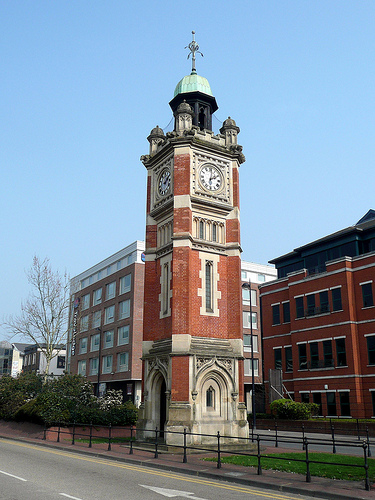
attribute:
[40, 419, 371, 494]
fence — metal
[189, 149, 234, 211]
clock — round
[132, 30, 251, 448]
tower — old, brick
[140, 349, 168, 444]
doorway — cement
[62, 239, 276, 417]
building — white, tan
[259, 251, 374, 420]
building — brown, red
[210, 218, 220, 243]
window — small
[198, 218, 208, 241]
window — small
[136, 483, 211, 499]
arrow — partial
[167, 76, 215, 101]
roof — blue, small, green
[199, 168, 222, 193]
numerals — black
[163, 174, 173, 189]
hands — black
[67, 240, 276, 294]
top of building — white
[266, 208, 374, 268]
roof — black